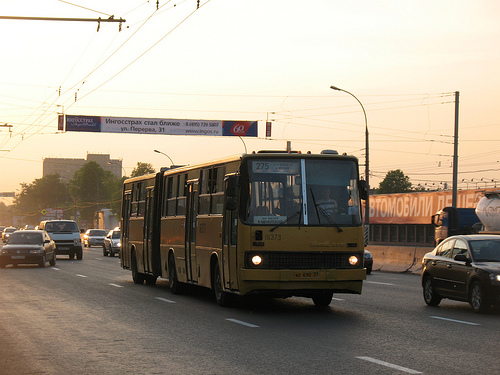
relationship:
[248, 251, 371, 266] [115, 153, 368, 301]
headlights of bus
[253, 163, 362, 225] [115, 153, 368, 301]
windshield of bus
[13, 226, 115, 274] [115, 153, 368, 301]
cars behind bus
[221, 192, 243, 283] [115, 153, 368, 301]
door of bus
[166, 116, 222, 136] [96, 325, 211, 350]
sign over road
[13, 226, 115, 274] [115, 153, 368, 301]
cars following bus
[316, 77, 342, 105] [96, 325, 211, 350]
light beside road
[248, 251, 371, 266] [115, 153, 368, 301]
headlights on bus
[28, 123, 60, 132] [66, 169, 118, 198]
sunlight on trees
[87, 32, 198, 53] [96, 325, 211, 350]
cables along road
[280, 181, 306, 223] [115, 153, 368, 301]
driver of bus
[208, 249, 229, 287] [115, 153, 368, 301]
tires on bus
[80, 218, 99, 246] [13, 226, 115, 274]
van behind cars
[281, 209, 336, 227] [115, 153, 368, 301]
blades on bus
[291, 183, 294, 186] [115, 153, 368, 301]
number on bus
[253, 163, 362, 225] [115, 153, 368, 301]
windshield on bus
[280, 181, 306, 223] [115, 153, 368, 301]
driver on bus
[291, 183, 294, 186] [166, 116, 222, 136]
number on sign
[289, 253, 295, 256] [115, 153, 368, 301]
grill on bus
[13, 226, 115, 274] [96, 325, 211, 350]
cars on road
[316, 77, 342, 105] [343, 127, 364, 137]
light on pole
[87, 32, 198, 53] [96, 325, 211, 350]
cables next to road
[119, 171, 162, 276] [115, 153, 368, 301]
cabin belonging to bus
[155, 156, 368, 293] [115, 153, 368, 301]
cabin belonging to bus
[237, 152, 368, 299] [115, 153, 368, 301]
front belonging to bus